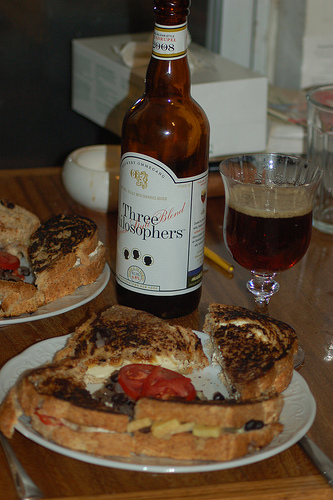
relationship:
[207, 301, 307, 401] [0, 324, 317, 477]
bread on plate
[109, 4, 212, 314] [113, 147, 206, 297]
bottle has label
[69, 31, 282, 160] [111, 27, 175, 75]
box of tissues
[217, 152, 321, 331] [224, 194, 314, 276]
glass has beer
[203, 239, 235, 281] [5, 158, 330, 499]
pencil on table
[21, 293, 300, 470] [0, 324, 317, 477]
sandwich on plate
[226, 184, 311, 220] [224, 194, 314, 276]
foam on beer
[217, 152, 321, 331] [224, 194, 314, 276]
glass full of beer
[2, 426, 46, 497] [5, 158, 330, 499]
silverware on table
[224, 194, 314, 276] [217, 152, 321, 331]
beer in glass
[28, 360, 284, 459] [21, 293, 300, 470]
half of sandwich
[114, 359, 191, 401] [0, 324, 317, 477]
tomato on plate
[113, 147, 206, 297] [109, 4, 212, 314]
label on bottle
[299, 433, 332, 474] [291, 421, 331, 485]
handle of utensil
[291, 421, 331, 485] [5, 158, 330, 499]
utensil on table